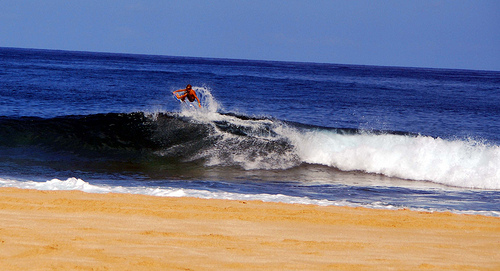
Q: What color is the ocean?
A: Blue.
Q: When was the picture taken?
A: During the daytime.